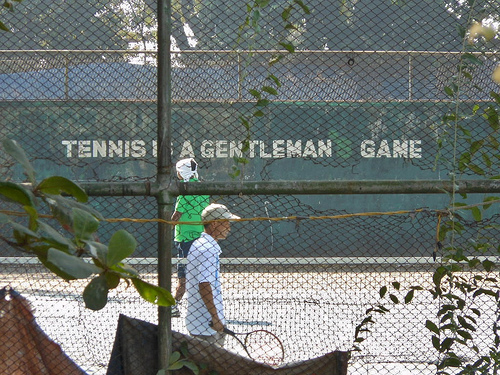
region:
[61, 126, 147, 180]
white letters that spell tennis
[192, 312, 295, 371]
black and red tennis racket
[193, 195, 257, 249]
person wearing a hat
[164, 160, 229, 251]
woman wearing a green shirt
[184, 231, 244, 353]
a white collared shirt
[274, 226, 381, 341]
a metal chain link fence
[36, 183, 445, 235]
electric chord running across fence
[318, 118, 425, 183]
white letters that s ay game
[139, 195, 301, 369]
man holding a tennis racket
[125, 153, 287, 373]
two people on a tennis court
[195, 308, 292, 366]
tennis racquet in hand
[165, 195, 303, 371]
person holding tennis racquet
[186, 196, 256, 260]
person wearing bright cap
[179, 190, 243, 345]
person wearing light colored shirt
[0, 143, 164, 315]
set of green leaves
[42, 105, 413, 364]
people in tennis court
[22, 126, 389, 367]
people in tennis court during daytime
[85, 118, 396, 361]
people outside on tennis court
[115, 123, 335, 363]
couple people on tennis court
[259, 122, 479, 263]
a hole in the fence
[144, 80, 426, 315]
a chain link fence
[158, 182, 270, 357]
a man in white shirt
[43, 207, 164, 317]
some large green leaves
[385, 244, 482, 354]
a few thin branches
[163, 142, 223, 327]
a man in bright colors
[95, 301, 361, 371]
a dark brown tarp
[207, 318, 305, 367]
a tennis racket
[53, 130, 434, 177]
large letters on wall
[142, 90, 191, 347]
an old metal pole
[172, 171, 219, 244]
a green shirt on a person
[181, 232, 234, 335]
a white shirt on a person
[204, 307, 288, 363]
a tennis racquet in a hand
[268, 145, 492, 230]
a rip in the netting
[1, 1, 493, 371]
netting on fence posts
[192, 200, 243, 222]
a tan cap on a person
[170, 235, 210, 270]
blue shorts on a person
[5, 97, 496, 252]
a tall green wall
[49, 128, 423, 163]
white words on a wall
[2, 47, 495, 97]
a fence above a wall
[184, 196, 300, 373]
Man playing tennis on court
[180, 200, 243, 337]
Man wearing light blue shirt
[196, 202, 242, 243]
Man wearing white cap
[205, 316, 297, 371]
Tennis racket in someone's hand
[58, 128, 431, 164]
Sign painted on tennis court wall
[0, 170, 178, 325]
Branches of bush outside tennis court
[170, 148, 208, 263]
Person wearing green shirt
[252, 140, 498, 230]
Large hole in tennis court fence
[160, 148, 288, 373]
Two people meeting for tennis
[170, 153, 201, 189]
Person wearing towel on head